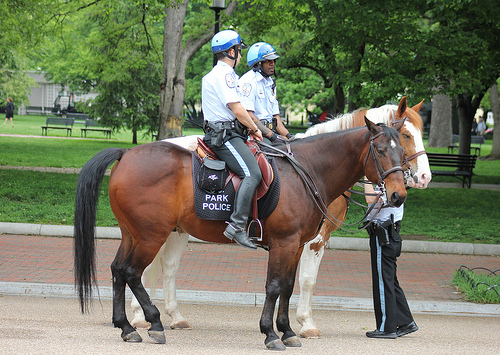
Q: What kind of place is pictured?
A: It is a park.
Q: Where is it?
A: This is at the park.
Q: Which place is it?
A: It is a park.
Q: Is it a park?
A: Yes, it is a park.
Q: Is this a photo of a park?
A: Yes, it is showing a park.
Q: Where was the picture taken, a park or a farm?
A: It was taken at a park.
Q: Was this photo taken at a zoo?
A: No, the picture was taken in a park.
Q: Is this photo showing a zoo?
A: No, the picture is showing a park.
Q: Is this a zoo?
A: No, it is a park.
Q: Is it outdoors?
A: Yes, it is outdoors.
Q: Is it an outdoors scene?
A: Yes, it is outdoors.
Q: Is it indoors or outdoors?
A: It is outdoors.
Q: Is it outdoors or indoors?
A: It is outdoors.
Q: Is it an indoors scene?
A: No, it is outdoors.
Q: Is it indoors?
A: No, it is outdoors.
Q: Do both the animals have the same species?
A: Yes, all the animals are horses.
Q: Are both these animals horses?
A: Yes, all the animals are horses.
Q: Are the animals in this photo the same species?
A: Yes, all the animals are horses.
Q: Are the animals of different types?
A: No, all the animals are horses.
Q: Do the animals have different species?
A: No, all the animals are horses.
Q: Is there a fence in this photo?
A: No, there are no fences.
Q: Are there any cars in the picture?
A: No, there are no cars.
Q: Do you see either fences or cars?
A: No, there are no cars or fences.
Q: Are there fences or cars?
A: No, there are no cars or fences.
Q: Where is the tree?
A: The tree is in the park.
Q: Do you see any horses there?
A: Yes, there is a horse.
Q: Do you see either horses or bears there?
A: Yes, there is a horse.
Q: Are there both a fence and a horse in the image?
A: No, there is a horse but no fences.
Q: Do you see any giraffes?
A: No, there are no giraffes.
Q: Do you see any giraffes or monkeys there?
A: No, there are no giraffes or monkeys.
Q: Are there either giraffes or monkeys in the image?
A: No, there are no giraffes or monkeys.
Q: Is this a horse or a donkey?
A: This is a horse.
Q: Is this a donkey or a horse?
A: This is a horse.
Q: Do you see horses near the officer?
A: Yes, there is a horse near the officer.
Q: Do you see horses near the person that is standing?
A: Yes, there is a horse near the officer.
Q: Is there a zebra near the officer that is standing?
A: No, there is a horse near the officer.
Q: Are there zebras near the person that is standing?
A: No, there is a horse near the officer.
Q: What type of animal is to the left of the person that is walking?
A: The animal is a horse.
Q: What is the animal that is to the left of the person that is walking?
A: The animal is a horse.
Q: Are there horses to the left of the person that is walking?
A: Yes, there is a horse to the left of the person.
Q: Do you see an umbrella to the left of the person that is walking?
A: No, there is a horse to the left of the person.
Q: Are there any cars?
A: No, there are no cars.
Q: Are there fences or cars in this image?
A: No, there are no cars or fences.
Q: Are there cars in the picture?
A: No, there are no cars.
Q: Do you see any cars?
A: No, there are no cars.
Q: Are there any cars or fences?
A: No, there are no cars or fences.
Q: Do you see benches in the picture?
A: Yes, there is a bench.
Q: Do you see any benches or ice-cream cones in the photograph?
A: Yes, there is a bench.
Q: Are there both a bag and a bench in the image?
A: Yes, there are both a bench and a bag.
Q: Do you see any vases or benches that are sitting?
A: Yes, the bench is sitting.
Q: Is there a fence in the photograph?
A: No, there are no fences.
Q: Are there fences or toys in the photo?
A: No, there are no fences or toys.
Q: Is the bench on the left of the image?
A: Yes, the bench is on the left of the image.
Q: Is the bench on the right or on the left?
A: The bench is on the left of the image.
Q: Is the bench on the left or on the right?
A: The bench is on the left of the image.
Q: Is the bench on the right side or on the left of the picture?
A: The bench is on the left of the image.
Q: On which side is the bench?
A: The bench is on the left of the image.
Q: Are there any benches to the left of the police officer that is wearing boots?
A: Yes, there is a bench to the left of the police officer.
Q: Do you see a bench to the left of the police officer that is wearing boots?
A: Yes, there is a bench to the left of the police officer.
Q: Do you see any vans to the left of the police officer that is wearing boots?
A: No, there is a bench to the left of the policeman.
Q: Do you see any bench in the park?
A: Yes, there is a bench in the park.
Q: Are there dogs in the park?
A: No, there is a bench in the park.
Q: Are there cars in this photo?
A: No, there are no cars.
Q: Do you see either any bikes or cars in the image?
A: No, there are no cars or bikes.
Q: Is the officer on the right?
A: Yes, the officer is on the right of the image.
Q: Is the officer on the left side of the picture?
A: No, the officer is on the right of the image.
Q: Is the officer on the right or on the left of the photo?
A: The officer is on the right of the image.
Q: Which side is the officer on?
A: The officer is on the right of the image.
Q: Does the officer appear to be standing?
A: Yes, the officer is standing.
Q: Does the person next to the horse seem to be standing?
A: Yes, the officer is standing.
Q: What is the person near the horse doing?
A: The officer is standing.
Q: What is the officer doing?
A: The officer is standing.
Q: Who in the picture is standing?
A: The officer is standing.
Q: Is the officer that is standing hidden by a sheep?
A: No, the officer is hidden by the horse.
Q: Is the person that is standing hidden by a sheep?
A: No, the officer is hidden by the horse.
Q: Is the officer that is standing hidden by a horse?
A: Yes, the officer is hidden by a horse.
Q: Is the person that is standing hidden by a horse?
A: Yes, the officer is hidden by a horse.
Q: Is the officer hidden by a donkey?
A: No, the officer is hidden by a horse.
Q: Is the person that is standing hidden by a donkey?
A: No, the officer is hidden by a horse.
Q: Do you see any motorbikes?
A: No, there are no motorbikes.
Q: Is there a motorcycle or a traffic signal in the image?
A: No, there are no motorcycles or traffic lights.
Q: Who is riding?
A: The police officer is riding.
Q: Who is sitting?
A: The police officer is sitting.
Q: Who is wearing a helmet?
A: The police officer is wearing a helmet.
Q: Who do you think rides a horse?
A: The police officer rides a horse.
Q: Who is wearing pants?
A: The policeman is wearing pants.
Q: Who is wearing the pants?
A: The policeman is wearing pants.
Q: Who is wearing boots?
A: The policeman is wearing boots.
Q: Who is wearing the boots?
A: The policeman is wearing boots.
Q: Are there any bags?
A: Yes, there is a bag.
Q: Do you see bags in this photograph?
A: Yes, there is a bag.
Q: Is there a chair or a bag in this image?
A: Yes, there is a bag.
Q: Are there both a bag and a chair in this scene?
A: No, there is a bag but no chairs.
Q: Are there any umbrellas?
A: No, there are no umbrellas.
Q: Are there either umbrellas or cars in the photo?
A: No, there are no umbrellas or cars.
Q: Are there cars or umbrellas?
A: No, there are no umbrellas or cars.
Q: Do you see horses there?
A: Yes, there is a horse.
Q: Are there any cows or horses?
A: Yes, there is a horse.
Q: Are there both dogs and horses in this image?
A: No, there is a horse but no dogs.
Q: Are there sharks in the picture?
A: No, there are no sharks.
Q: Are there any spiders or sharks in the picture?
A: No, there are no sharks or spiders.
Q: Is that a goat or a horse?
A: That is a horse.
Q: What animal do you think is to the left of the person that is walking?
A: The animal is a horse.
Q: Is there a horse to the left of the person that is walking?
A: Yes, there is a horse to the left of the person.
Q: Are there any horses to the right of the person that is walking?
A: No, the horse is to the left of the person.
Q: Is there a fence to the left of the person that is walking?
A: No, there is a horse to the left of the person.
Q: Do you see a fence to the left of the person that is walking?
A: No, there is a horse to the left of the person.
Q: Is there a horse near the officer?
A: Yes, there is a horse near the officer.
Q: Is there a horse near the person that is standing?
A: Yes, there is a horse near the officer.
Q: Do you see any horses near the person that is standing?
A: Yes, there is a horse near the officer.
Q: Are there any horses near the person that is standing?
A: Yes, there is a horse near the officer.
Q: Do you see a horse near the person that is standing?
A: Yes, there is a horse near the officer.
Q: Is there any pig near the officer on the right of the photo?
A: No, there is a horse near the officer.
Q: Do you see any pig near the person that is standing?
A: No, there is a horse near the officer.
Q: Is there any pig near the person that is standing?
A: No, there is a horse near the officer.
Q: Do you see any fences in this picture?
A: No, there are no fences.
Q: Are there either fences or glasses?
A: No, there are no fences or glasses.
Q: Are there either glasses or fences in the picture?
A: No, there are no fences or glasses.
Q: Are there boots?
A: Yes, there are boots.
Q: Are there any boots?
A: Yes, there are boots.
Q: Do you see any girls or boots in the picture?
A: Yes, there are boots.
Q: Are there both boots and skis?
A: No, there are boots but no skis.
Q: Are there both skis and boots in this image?
A: No, there are boots but no skis.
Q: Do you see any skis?
A: No, there are no skis.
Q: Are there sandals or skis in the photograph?
A: No, there are no skis or sandals.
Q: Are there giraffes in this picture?
A: No, there are no giraffes.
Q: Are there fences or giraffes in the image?
A: No, there are no giraffes or fences.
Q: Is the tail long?
A: Yes, the tail is long.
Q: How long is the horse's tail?
A: The tail is long.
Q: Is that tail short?
A: No, the tail is long.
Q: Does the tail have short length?
A: No, the tail is long.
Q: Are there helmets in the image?
A: Yes, there is a helmet.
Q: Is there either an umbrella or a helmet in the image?
A: Yes, there is a helmet.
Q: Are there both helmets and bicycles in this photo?
A: No, there is a helmet but no bikes.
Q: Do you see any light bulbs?
A: No, there are no light bulbs.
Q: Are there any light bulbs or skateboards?
A: No, there are no light bulbs or skateboards.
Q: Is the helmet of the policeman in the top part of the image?
A: Yes, the helmet is in the top of the image.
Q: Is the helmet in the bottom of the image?
A: No, the helmet is in the top of the image.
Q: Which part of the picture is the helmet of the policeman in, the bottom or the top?
A: The helmet is in the top of the image.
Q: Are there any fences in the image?
A: No, there are no fences.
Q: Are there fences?
A: No, there are no fences.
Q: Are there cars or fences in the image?
A: No, there are no fences or cars.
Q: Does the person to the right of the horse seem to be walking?
A: Yes, the person is walking.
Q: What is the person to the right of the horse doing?
A: The person is walking.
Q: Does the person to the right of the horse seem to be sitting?
A: No, the person is walking.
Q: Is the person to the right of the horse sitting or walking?
A: The person is walking.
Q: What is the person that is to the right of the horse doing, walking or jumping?
A: The person is walking.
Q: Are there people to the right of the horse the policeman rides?
A: Yes, there is a person to the right of the horse.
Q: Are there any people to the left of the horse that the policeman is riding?
A: No, the person is to the right of the horse.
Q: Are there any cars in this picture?
A: No, there are no cars.